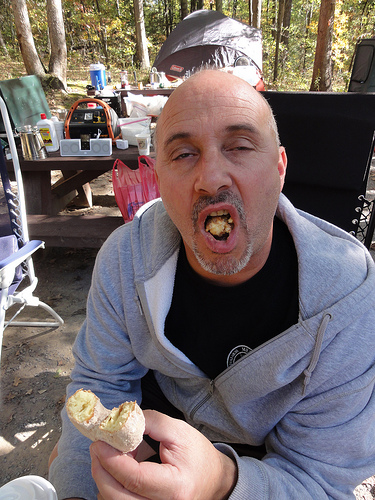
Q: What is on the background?
A: Trees.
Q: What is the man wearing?
A: Jacket.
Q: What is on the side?
A: Table.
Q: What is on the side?
A: Chair.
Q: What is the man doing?
A: Opening.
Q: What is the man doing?
A: Eating.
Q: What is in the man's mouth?
A: Food.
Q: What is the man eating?
A: A donut.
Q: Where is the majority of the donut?
A: In the man's hand.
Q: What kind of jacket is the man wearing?
A: A sweatshirt.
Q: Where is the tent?
A: In front of the trees.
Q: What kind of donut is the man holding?
A: Powdered donut.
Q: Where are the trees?
A: Behind the tent.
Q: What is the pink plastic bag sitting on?
A: Picnic table.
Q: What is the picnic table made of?
A: Wood.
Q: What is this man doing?
A: Eating a donut.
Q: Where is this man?
A: In camping area.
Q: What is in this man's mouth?
A: Donut.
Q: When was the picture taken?
A: Daytime.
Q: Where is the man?
A: Campground.